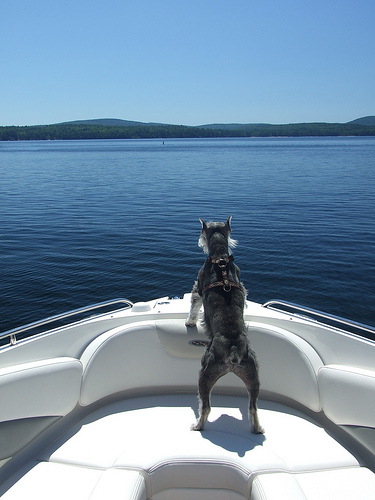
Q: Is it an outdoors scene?
A: Yes, it is outdoors.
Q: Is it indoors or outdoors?
A: It is outdoors.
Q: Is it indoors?
A: No, it is outdoors.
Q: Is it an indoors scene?
A: No, it is outdoors.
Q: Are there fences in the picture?
A: No, there are no fences.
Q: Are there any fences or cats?
A: No, there are no fences or cats.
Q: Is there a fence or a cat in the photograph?
A: No, there are no fences or cats.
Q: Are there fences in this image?
A: No, there are no fences.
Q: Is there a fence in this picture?
A: No, there are no fences.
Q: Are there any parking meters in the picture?
A: No, there are no parking meters.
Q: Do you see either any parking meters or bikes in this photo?
A: No, there are no parking meters or bikes.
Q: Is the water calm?
A: Yes, the water is calm.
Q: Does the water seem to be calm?
A: Yes, the water is calm.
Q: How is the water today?
A: The water is calm.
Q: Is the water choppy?
A: No, the water is calm.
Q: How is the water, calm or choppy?
A: The water is calm.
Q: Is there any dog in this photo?
A: Yes, there is a dog.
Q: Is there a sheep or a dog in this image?
A: Yes, there is a dog.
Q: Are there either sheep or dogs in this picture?
A: Yes, there is a dog.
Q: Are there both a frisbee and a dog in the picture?
A: No, there is a dog but no frisbees.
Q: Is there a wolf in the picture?
A: No, there are no wolves.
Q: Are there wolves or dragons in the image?
A: No, there are no wolves or dragons.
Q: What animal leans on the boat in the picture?
A: The dog leans on the boat.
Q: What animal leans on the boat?
A: The dog leans on the boat.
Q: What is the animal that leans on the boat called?
A: The animal is a dog.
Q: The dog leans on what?
A: The dog leans on the boat.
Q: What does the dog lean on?
A: The dog leans on the boat.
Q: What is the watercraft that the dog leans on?
A: The watercraft is a boat.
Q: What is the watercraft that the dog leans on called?
A: The watercraft is a boat.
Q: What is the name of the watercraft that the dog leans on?
A: The watercraft is a boat.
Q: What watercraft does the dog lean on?
A: The dog leans on the boat.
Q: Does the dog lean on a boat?
A: Yes, the dog leans on a boat.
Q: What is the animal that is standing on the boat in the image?
A: The animal is a dog.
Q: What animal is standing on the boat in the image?
A: The animal is a dog.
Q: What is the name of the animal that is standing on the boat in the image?
A: The animal is a dog.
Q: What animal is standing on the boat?
A: The animal is a dog.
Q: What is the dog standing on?
A: The dog is standing on the boat.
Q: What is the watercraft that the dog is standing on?
A: The watercraft is a boat.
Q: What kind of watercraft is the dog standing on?
A: The dog is standing on the boat.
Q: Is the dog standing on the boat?
A: Yes, the dog is standing on the boat.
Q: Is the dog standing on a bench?
A: No, the dog is standing on the boat.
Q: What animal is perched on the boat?
A: The dog is perched on the boat.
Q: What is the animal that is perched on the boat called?
A: The animal is a dog.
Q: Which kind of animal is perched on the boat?
A: The animal is a dog.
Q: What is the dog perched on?
A: The dog is perched on the boat.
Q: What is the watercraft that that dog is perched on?
A: The watercraft is a boat.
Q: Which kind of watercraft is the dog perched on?
A: The dog is perched on the boat.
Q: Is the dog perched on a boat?
A: Yes, the dog is perched on a boat.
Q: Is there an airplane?
A: No, there are no airplanes.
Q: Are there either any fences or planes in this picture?
A: No, there are no planes or fences.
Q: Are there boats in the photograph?
A: Yes, there is a boat.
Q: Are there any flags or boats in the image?
A: Yes, there is a boat.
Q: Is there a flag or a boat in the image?
A: Yes, there is a boat.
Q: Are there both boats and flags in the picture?
A: No, there is a boat but no flags.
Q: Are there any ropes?
A: No, there are no ropes.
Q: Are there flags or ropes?
A: No, there are no ropes or flags.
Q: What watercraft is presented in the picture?
A: The watercraft is a boat.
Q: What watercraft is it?
A: The watercraft is a boat.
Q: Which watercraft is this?
A: That is a boat.